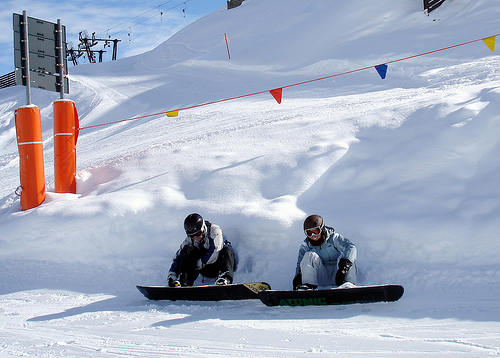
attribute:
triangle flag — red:
[268, 86, 283, 103]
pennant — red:
[269, 78, 291, 104]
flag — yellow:
[260, 83, 290, 111]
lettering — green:
[276, 295, 327, 305]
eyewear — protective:
[177, 229, 212, 241]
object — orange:
[14, 102, 45, 209]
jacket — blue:
[302, 240, 357, 272]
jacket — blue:
[165, 233, 240, 275]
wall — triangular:
[287, 85, 352, 159]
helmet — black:
[181, 210, 213, 244]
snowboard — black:
[258, 286, 408, 307]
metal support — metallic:
[74, 36, 119, 44]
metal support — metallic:
[67, 46, 105, 54]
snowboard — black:
[137, 283, 271, 301]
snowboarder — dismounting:
[165, 213, 240, 283]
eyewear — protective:
[302, 225, 324, 247]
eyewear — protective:
[180, 227, 205, 240]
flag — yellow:
[164, 103, 187, 123]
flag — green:
[266, 85, 288, 105]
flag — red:
[372, 60, 389, 80]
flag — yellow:
[479, 30, 496, 55]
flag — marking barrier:
[478, 32, 493, 56]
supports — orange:
[4, 78, 101, 247]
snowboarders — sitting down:
[159, 208, 364, 290]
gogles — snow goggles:
[304, 226, 330, 235]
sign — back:
[12, 12, 69, 93]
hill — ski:
[59, 77, 499, 213]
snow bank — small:
[206, 117, 421, 219]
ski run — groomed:
[163, 97, 432, 258]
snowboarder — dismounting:
[291, 213, 359, 290]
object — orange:
[52, 97, 79, 191]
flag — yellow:
[483, 35, 499, 58]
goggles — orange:
[300, 217, 324, 238]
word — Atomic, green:
[277, 290, 333, 310]